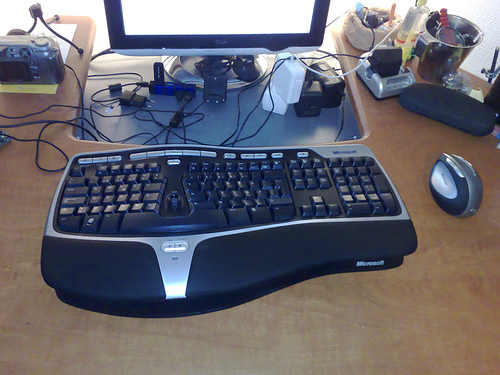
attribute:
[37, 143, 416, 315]
keyboard — gaming , wireless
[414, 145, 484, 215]
mouse — wireless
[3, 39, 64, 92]
camera — Digital 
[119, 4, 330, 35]
monitor — computer, LCD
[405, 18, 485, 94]
cup — holding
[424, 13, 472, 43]
supplies — office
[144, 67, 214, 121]
slots — Usb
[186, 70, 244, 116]
outlet — DC 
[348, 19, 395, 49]
ashtray — back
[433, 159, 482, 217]
mouse — wireless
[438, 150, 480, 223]
mouse — wireless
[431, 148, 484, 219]
mouse — wireless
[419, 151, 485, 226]
mouse — wireless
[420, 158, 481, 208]
mouse — wireless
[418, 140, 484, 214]
mouse — optical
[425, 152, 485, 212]
mouse — optical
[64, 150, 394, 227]
keyboard — Computer 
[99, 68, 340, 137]
cables — Electronics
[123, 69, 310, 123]
cords —  power 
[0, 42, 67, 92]
camera — Digital  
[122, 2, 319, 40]
monitor — Computer  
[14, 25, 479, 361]
desk — computer, Wood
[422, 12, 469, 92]
cup — Metal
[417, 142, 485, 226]
mouse — computer, Wireless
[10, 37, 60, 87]
camera — Digital ,  wire 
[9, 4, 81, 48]
tripod — small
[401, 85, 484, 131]
case — Black 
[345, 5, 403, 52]
bowl — small